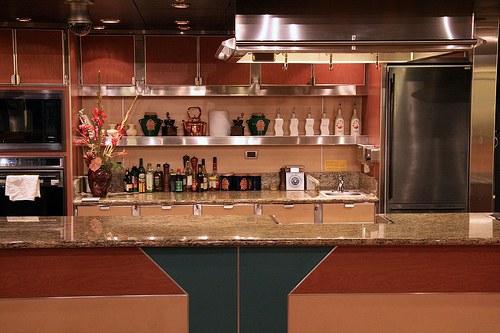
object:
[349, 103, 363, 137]
bottles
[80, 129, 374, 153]
shelf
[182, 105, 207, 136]
teapot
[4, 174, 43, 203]
kitchen towel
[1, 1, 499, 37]
ceiling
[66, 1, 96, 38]
recessed lighting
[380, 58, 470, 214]
refrigerator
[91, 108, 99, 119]
flowers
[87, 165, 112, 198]
vase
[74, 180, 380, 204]
counter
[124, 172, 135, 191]
condiments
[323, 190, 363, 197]
sink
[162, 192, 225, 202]
reflection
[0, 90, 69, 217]
appliance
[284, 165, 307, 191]
scale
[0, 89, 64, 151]
microwave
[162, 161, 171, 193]
pepper grinder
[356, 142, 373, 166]
silver box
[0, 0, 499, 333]
kitchen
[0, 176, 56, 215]
oven door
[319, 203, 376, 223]
drawers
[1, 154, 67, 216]
oven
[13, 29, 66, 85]
cabinets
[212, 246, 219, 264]
blue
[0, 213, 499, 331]
counter